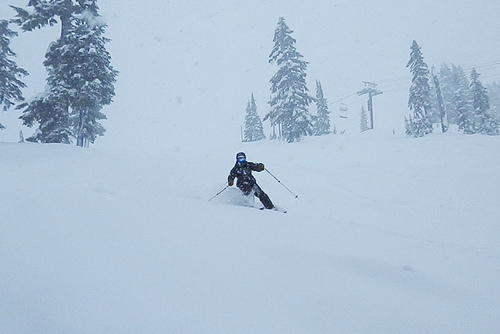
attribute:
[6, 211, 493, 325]
snow — white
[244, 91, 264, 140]
pine tree — snow covered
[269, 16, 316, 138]
pine tree — snow covered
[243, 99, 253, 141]
pine tree — snow covered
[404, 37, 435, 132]
pine tree — snow covered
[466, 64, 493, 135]
pine tree — snow covered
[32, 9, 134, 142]
tree — snow covered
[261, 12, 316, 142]
pine tree — snow covered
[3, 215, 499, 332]
snow — white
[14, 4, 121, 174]
pine tree — snow covered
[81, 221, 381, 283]
snow — white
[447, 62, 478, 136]
tree — snow covered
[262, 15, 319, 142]
tree — snow covered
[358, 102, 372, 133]
pine tree — snow-covered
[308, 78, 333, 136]
pine tree — snow-covered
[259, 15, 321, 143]
pine tree — snow-covered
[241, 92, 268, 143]
pine tree — snow-covered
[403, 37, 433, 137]
pine tree — snow-covered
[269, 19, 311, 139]
snow — white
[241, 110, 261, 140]
snow — white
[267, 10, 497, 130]
snow — white